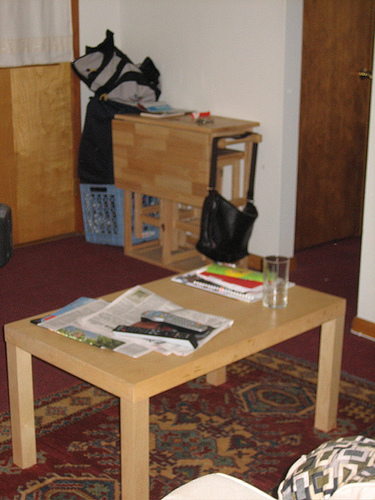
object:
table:
[5, 261, 350, 499]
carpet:
[0, 230, 374, 499]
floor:
[2, 229, 374, 499]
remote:
[140, 307, 212, 335]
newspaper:
[81, 281, 236, 360]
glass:
[260, 249, 291, 313]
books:
[201, 251, 279, 293]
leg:
[314, 303, 346, 435]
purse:
[195, 127, 260, 266]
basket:
[78, 178, 160, 250]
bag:
[70, 28, 162, 111]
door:
[295, 1, 375, 255]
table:
[108, 105, 262, 278]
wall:
[80, 2, 305, 262]